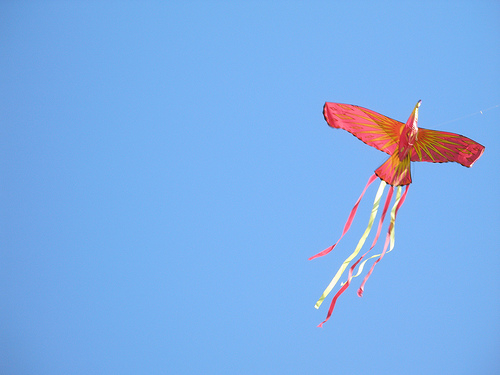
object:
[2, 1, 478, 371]
sky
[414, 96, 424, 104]
point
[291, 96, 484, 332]
kite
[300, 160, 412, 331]
end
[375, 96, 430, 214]
body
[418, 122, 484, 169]
wing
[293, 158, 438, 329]
tail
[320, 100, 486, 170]
wings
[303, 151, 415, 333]
tail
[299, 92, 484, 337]
kite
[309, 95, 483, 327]
kite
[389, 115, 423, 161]
body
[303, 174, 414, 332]
ribbons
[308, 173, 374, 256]
string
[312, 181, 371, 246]
string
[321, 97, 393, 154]
wing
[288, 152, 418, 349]
tail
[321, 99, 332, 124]
tip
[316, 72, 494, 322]
design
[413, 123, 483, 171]
wing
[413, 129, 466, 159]
design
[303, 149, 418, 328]
tail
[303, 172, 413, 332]
streamers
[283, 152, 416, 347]
tail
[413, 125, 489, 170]
wing